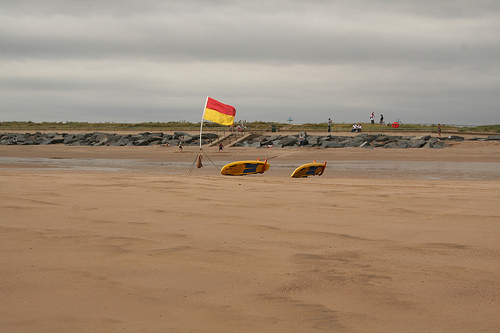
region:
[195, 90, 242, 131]
Red and yellow flag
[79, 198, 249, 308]
Large body of sand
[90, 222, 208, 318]
Body of sand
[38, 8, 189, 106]
The sky is cloudy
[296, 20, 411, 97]
The sky is cloudy and dark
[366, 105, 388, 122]
Couple of people in the background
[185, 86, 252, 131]
red and yellow flag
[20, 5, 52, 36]
white clouds in blue sky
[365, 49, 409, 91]
white clouds in blue sky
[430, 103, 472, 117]
white clouds in blue sky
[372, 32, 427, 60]
white clouds in blue sky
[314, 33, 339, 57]
white clouds in blue sky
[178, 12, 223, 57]
white clouds in blue sky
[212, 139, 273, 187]
yellow raft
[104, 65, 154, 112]
white clouds in blue sky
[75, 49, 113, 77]
white clouds in blue sky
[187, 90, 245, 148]
flag in the sand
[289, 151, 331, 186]
surfboard in the sand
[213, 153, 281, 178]
surfboard in the sand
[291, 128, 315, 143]
people sitting on the rocks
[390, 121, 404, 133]
red kite on the ground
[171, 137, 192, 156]
person standing in the sand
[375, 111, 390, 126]
person riding a bike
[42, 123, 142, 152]
rocks at the edge of the sand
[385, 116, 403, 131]
red cloth in the sand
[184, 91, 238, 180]
yellow and red flag on sand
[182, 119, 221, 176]
white flag support pole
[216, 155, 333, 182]
two yellow surfboards on sand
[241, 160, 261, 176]
blue design on yellow surfboard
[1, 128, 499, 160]
log narrow strip of grey rock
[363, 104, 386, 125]
two people standing on surface beyond rock formation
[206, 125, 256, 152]
staircase in middle of rock formation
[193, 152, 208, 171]
sandbag at bottom of flag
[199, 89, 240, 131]
rd and yellow flag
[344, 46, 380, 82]
white clouds in blue sky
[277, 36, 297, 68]
white clouds in blue sky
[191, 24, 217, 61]
white clouds in blue sky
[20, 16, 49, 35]
white clouds in blue sky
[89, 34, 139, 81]
white clouds in blue sky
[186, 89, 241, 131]
red and yellow flag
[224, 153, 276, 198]
yellow raft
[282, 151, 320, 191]
yellow raft